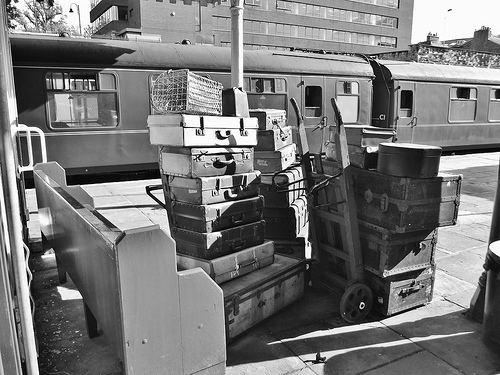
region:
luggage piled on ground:
[153, 70, 297, 367]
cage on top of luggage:
[134, 56, 229, 133]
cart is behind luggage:
[287, 102, 396, 345]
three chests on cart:
[350, 157, 430, 327]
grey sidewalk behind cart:
[433, 197, 490, 259]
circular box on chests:
[359, 105, 464, 197]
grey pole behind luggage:
[212, 0, 248, 85]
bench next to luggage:
[72, 173, 221, 373]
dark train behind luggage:
[28, 36, 497, 156]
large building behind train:
[119, 7, 412, 64]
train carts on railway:
[0, 31, 488, 182]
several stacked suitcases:
[141, 49, 308, 331]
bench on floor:
[34, 163, 232, 373]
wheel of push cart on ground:
[326, 280, 383, 347]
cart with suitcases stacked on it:
[280, 88, 379, 323]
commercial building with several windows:
[82, 0, 417, 50]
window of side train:
[440, 82, 485, 125]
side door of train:
[384, 79, 423, 146]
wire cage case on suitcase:
[144, 68, 237, 117]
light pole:
[223, 3, 262, 82]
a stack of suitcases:
[146, 90, 319, 319]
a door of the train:
[396, 88, 409, 142]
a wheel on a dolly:
[345, 281, 380, 321]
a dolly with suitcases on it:
[297, 100, 443, 330]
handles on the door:
[21, 123, 57, 164]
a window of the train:
[48, 75, 120, 127]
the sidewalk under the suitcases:
[279, 311, 417, 371]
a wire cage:
[158, 68, 220, 114]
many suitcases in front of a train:
[153, 82, 440, 312]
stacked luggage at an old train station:
[10, 30, 493, 362]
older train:
[5, 20, 496, 146]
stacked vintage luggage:
[145, 70, 461, 328]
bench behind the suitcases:
[30, 147, 228, 362]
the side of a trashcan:
[471, 230, 496, 341]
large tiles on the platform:
[28, 158, 496, 368]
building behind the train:
[97, 7, 412, 62]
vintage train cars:
[3, 30, 494, 178]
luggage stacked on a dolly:
[284, 93, 461, 314]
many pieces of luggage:
[141, 110, 300, 313]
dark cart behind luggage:
[276, 159, 378, 336]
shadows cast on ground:
[310, 310, 495, 372]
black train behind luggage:
[8, 18, 495, 170]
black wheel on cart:
[341, 289, 373, 318]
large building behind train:
[116, 0, 390, 50]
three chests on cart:
[316, 145, 447, 312]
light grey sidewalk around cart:
[453, 155, 485, 281]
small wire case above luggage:
[146, 69, 214, 119]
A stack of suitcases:
[145, 60, 308, 346]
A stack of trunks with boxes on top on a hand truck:
[309, 104, 476, 316]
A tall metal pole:
[220, 0, 265, 92]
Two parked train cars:
[3, 27, 498, 178]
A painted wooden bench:
[26, 149, 231, 374]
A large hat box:
[375, 140, 446, 183]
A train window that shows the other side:
[39, 65, 125, 135]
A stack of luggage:
[245, 103, 311, 270]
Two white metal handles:
[12, 116, 49, 173]